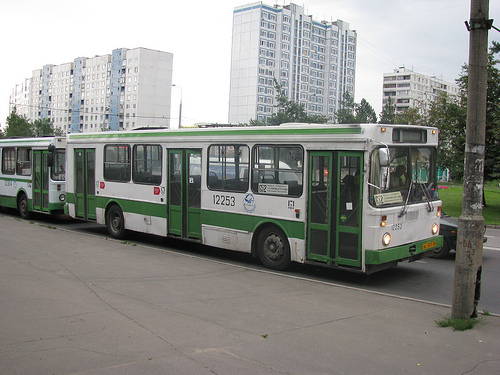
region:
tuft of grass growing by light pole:
[434, 315, 479, 330]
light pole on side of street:
[448, 0, 490, 320]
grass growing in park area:
[437, 176, 498, 227]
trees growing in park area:
[260, 42, 496, 198]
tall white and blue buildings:
[1, 0, 463, 133]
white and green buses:
[2, 118, 444, 290]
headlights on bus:
[377, 218, 442, 245]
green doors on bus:
[303, 145, 367, 268]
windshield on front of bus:
[370, 147, 441, 207]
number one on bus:
[209, 192, 216, 208]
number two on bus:
[216, 193, 222, 211]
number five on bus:
[224, 195, 230, 207]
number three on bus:
[229, 195, 236, 209]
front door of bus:
[303, 144, 365, 276]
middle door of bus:
[163, 148, 205, 245]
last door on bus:
[67, 145, 102, 224]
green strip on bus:
[66, 122, 369, 143]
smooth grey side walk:
[171, 290, 251, 327]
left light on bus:
[380, 230, 396, 250]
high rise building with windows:
[226, 0, 367, 123]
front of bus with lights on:
[366, 112, 447, 283]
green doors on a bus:
[302, 123, 371, 283]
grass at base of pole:
[441, 306, 487, 338]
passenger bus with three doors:
[62, 108, 443, 278]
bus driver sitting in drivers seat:
[384, 153, 413, 196]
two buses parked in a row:
[2, 110, 457, 285]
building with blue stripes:
[13, 39, 182, 131]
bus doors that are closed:
[299, 130, 374, 287]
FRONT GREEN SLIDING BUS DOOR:
[306, 148, 366, 271]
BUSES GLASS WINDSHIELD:
[368, 145, 439, 211]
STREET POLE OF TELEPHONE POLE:
[456, 2, 494, 329]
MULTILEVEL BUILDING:
[230, 0, 355, 122]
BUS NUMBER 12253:
[211, 193, 238, 208]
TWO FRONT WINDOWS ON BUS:
[207, 142, 308, 199]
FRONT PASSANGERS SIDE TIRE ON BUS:
[249, 225, 294, 273]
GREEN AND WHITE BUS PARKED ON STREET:
[63, 126, 443, 278]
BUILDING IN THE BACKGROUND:
[9, 50, 174, 133]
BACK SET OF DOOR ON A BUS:
[71, 145, 97, 220]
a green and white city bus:
[65, 119, 451, 288]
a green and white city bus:
[1, 118, 66, 235]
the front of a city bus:
[369, 125, 441, 261]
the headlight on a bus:
[381, 230, 393, 247]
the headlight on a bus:
[429, 222, 439, 234]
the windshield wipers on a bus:
[397, 169, 432, 216]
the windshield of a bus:
[372, 147, 437, 207]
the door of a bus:
[307, 148, 364, 266]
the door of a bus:
[169, 147, 199, 241]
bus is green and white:
[0, 121, 446, 277]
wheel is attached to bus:
[254, 220, 291, 274]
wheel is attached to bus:
[104, 202, 126, 238]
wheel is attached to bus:
[14, 190, 31, 220]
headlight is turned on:
[382, 230, 392, 247]